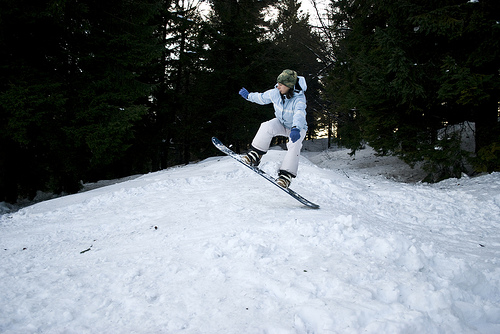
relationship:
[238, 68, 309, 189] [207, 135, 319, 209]
girl riding snowboard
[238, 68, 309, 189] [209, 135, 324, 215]
girl performing trick on snowboard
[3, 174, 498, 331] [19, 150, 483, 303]
snow of hill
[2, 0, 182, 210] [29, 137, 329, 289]
tree growing next to ski slope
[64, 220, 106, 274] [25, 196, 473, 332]
twigs in snow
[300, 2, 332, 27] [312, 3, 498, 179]
cloudy sky behind tree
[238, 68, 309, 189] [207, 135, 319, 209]
girl on snowboard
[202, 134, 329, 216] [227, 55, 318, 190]
snowboard under person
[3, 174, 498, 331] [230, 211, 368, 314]
snow has marks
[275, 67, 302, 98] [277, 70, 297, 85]
head has beanie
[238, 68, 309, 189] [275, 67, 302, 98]
girl has head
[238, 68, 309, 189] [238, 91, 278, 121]
girl has glove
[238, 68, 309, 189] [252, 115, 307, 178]
girl has pants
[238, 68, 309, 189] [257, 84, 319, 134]
girl has jacket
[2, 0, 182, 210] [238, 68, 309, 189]
tree are behind girl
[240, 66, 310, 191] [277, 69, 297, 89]
girl has beanie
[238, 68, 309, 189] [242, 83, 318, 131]
girl has coat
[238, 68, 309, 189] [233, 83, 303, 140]
girl has gloves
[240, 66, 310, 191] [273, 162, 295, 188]
girl has shoe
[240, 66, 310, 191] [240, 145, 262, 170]
girl has shoe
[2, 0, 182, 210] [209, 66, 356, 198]
tree are behind girl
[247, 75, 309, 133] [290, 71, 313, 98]
hoodie has hoodie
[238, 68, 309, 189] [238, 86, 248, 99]
girl has glove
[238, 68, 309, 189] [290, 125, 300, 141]
girl has glove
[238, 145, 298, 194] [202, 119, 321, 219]
boots are on board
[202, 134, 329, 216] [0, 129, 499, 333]
snowboard jumping over hill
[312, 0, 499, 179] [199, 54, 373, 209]
tree are behind girl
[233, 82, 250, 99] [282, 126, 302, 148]
glove on hand